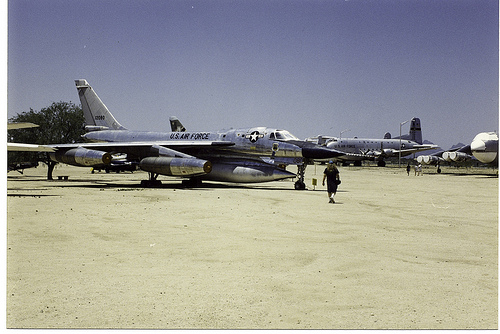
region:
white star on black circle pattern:
[248, 131, 260, 143]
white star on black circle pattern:
[246, 127, 263, 142]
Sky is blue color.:
[105, 10, 473, 71]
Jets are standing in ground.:
[90, 117, 466, 202]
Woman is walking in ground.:
[306, 155, 346, 220]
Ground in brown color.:
[173, 200, 496, 316]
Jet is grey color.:
[71, 77, 476, 207]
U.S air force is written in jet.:
[164, 127, 213, 144]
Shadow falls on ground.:
[20, 173, 165, 205]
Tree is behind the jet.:
[25, 103, 100, 158]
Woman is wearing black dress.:
[319, 160, 344, 204]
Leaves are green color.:
[27, 111, 79, 136]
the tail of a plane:
[68, 70, 135, 147]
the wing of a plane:
[6, 129, 236, 166]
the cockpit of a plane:
[268, 122, 298, 144]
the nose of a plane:
[300, 137, 382, 172]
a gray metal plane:
[11, 72, 385, 209]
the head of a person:
[325, 156, 338, 171]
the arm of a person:
[321, 164, 329, 182]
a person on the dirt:
[317, 155, 347, 205]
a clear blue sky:
[6, 0, 498, 155]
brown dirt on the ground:
[6, 163, 496, 327]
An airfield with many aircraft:
[0, 82, 490, 235]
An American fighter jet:
[44, 85, 410, 193]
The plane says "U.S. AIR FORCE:
[167, 129, 215, 145]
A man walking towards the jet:
[317, 157, 347, 212]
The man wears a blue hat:
[329, 158, 335, 163]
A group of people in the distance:
[404, 162, 444, 174]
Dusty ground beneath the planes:
[57, 203, 454, 325]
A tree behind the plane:
[28, 105, 82, 141]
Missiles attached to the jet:
[204, 156, 281, 186]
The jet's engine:
[62, 141, 109, 170]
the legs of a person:
[324, 178, 341, 201]